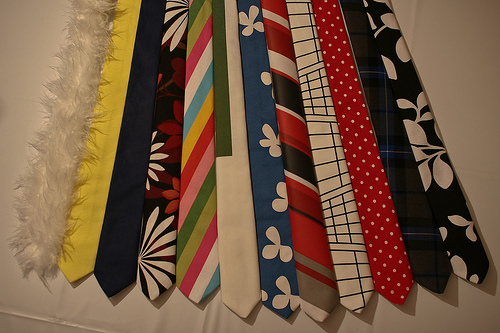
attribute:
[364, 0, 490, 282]
necktie — crazy patterned, black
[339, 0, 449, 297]
necktie — crazy patterned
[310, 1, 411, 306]
necktie — crazy patterned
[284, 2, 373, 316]
necktie — white, black, crazy patterned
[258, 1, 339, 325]
necktie — crazy patterned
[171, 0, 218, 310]
tie — striped, cotton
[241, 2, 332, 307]
tie — striped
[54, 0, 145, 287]
neck tie — lemon yellow, silk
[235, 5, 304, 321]
blue necktie — white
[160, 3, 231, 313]
tie — blue, yellow, red, pink, green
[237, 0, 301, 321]
necktie — blue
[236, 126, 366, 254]
necktie — red, black, white, orange, grey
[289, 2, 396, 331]
tie — white, black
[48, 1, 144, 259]
tie — cotton, yellow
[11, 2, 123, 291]
necktie — white, fake fur, fuzzy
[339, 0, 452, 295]
tie — blue, plaid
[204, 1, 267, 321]
tie — green, white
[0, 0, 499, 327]
background — white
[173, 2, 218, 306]
necktie — white, yellow, blue, red, green, striped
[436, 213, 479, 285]
object — white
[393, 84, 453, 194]
object — white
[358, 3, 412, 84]
object — white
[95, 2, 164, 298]
tie — black